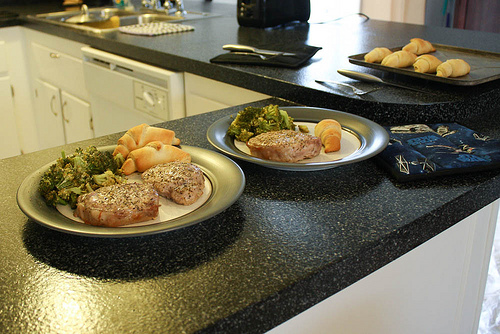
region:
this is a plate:
[10, 116, 255, 233]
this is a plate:
[199, 65, 393, 185]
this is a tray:
[339, 9, 491, 116]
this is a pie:
[429, 53, 474, 85]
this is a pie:
[406, 51, 448, 80]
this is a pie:
[376, 36, 414, 76]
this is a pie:
[353, 38, 395, 75]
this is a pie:
[400, 28, 443, 59]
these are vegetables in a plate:
[33, 143, 115, 201]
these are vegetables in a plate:
[231, 92, 298, 139]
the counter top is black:
[92, 257, 290, 313]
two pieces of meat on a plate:
[74, 164, 209, 221]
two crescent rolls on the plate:
[114, 119, 188, 165]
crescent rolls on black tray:
[356, 37, 478, 81]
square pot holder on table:
[386, 120, 491, 177]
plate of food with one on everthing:
[228, 104, 342, 162]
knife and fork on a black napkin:
[210, 39, 320, 67]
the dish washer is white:
[80, 47, 184, 124]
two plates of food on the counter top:
[19, 99, 388, 237]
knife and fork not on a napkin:
[313, 67, 410, 101]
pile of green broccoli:
[36, 149, 129, 198]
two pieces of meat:
[73, 160, 206, 229]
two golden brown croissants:
[108, 122, 190, 173]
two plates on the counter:
[13, 97, 404, 257]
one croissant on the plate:
[316, 116, 343, 151]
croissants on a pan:
[345, 35, 498, 93]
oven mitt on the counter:
[380, 120, 498, 183]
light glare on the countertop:
[33, 269, 105, 332]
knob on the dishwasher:
[138, 85, 159, 107]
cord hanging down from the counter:
[306, 12, 380, 25]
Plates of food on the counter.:
[17, 101, 388, 233]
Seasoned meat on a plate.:
[82, 162, 202, 224]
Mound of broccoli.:
[44, 147, 124, 199]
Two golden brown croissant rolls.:
[116, 122, 196, 171]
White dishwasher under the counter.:
[77, 47, 192, 133]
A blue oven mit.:
[381, 122, 495, 184]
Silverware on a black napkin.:
[212, 29, 320, 74]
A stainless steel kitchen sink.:
[28, 6, 183, 36]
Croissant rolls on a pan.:
[346, 38, 497, 88]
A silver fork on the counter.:
[310, 77, 377, 100]